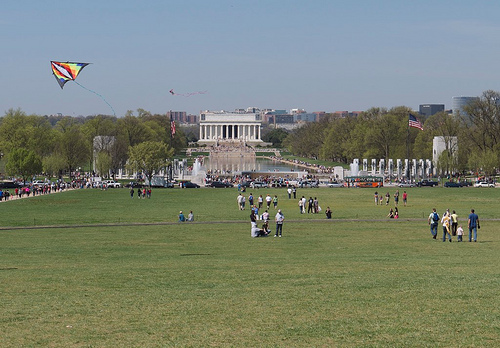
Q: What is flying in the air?
A: Kites.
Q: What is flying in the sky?
A: Kite.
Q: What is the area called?
A: National Mall.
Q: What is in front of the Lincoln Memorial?
A: Reflecting pool.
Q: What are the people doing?
A: Walking.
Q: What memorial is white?
A: Lincoln Memorial.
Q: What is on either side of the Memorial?
A: Trees.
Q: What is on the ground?
A: Grass.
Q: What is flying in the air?
A: Kites.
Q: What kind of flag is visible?
A: An american flag.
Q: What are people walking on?
A: A sidewalk.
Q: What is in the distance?
A: High rises.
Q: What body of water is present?
A: A pond.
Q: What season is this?
A: Spring.